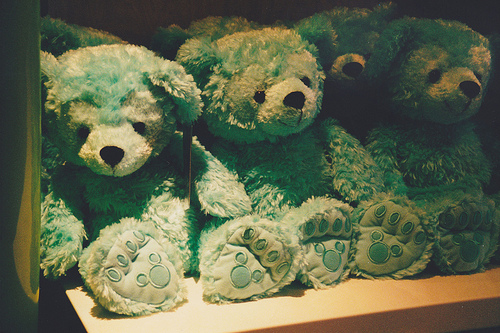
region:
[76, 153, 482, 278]
teddy bears ons helf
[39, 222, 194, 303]
foot of the bear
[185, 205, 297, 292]
foot of the bear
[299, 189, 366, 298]
foot of the bear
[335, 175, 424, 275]
foot of the bear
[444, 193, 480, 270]
foot of the bear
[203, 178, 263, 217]
paw of the bear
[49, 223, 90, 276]
paw of the bear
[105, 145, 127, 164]
nose of the bear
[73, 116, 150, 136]
eyes of the bear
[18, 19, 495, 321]
three blue teddy bears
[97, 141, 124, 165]
small black nose of blue teddy bear on left side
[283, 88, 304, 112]
small black nose of blue teddy bear on the middle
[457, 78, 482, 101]
small black nose of blue teddy bear on right side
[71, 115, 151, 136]
two small black eyes of blue teddy bear in the left side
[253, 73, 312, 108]
two small black eyes of blue teddy bear in the middle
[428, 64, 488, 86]
two small black eyes of blue teddy bear in the right side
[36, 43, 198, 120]
two small furry ears of blue teddy bear in left side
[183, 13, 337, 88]
two small furry ears of blue teddy bear in the middle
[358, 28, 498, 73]
two small furry ears of blue teddy bear inright side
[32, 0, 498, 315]
the group of stuffed animals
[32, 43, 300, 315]
the stuffed teddy bear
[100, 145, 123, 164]
the nose on the bear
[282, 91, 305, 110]
the nose on the bear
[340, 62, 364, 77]
the nose on the bear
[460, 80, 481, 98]
the nose on the bear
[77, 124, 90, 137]
teh eye on the bear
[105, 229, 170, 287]
the markings under the bear's foot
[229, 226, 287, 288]
the markings under the bear's foot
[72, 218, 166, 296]
foot of the bear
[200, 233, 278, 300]
foot of the bear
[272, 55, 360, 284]
foot of the bear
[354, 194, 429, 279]
foot of the bear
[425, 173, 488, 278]
foot of the bear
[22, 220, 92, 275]
arm of the bear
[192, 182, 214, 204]
paw of the bear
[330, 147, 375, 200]
paw of the bear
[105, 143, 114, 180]
nose of the bear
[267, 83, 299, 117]
nose of the bear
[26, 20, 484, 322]
A selection of blue teddy bears